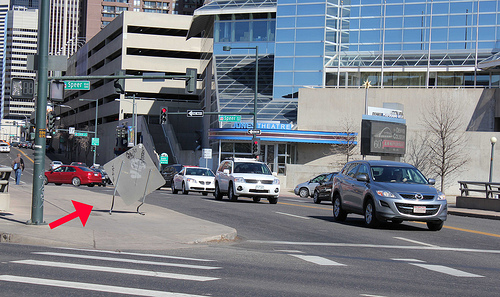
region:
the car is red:
[41, 155, 101, 192]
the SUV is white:
[206, 142, 295, 207]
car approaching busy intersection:
[330, 158, 447, 230]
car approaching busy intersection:
[292, 172, 329, 197]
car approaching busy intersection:
[311, 169, 334, 201]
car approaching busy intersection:
[213, 158, 284, 203]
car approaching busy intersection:
[170, 165, 216, 194]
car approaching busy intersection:
[41, 163, 103, 188]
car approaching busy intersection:
[157, 163, 182, 190]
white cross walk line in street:
[15, 253, 217, 280]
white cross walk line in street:
[30, 245, 225, 271]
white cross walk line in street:
[282, 247, 350, 269]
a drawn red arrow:
[45, 195, 92, 230]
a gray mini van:
[331, 157, 447, 228]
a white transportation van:
[216, 155, 279, 200]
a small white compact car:
[170, 163, 212, 191]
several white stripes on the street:
[0, 237, 216, 294]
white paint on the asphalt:
[292, 249, 340, 268]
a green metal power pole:
[32, 0, 48, 229]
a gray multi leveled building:
[63, 12, 209, 172]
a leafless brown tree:
[422, 102, 469, 212]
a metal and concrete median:
[456, 177, 498, 212]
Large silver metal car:
[329, 157, 445, 233]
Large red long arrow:
[40, 192, 97, 236]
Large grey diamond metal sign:
[98, 141, 170, 206]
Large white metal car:
[214, 156, 279, 203]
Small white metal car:
[166, 166, 213, 191]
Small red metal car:
[41, 158, 106, 185]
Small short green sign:
[66, 76, 88, 93]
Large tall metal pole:
[30, 0, 50, 220]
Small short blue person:
[10, 155, 23, 182]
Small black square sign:
[355, 119, 412, 159]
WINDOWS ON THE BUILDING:
[401, 26, 428, 43]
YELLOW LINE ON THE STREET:
[458, 227, 487, 234]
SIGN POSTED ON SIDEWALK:
[111, 143, 172, 213]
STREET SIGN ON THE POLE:
[67, 79, 89, 87]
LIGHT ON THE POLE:
[488, 133, 495, 143]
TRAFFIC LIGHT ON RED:
[159, 101, 170, 124]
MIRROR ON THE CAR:
[356, 175, 368, 180]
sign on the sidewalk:
[93, 138, 190, 218]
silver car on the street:
[333, 152, 442, 233]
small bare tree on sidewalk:
[422, 105, 472, 178]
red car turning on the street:
[46, 155, 103, 187]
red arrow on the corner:
[43, 196, 97, 235]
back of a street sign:
[100, 141, 167, 206]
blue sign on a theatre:
[227, 117, 296, 133]